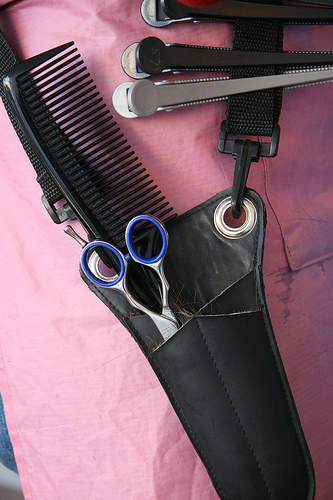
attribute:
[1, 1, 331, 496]
case — black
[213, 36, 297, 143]
strap — nylon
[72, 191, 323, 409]
pouch — black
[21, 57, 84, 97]
tooth — black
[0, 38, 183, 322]
comb — black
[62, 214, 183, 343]
scissors — blue handled, pair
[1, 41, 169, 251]
comb — black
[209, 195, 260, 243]
ring — metal 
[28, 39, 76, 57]
tooth — black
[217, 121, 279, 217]
plastic clip — attached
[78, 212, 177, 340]
scissors — black 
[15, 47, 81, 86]
tooth — black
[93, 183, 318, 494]
pouch — black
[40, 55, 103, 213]
comb — black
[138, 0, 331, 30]
hair clip — black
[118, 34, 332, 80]
hair clip — black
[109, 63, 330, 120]
hair clip — silver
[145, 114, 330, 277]
apron — pink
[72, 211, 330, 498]
pouch — black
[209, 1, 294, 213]
strap — black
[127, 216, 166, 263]
ring — blue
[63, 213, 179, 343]
scissor — blue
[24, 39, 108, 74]
tooth — black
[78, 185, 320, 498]
case — black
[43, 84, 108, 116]
tooth — black